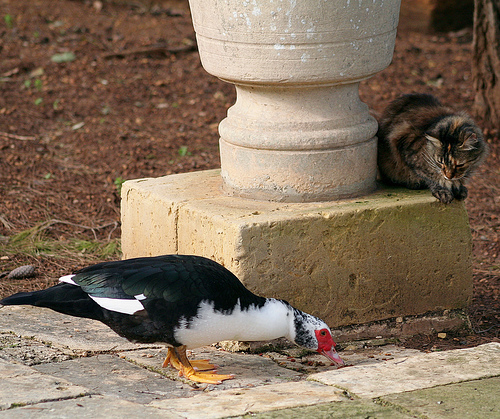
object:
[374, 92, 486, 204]
cat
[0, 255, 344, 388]
duck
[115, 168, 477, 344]
block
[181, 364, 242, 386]
feet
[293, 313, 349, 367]
head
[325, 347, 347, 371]
beak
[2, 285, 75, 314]
tail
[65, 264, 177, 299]
wings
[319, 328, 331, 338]
right eye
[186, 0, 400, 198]
pot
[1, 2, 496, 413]
ground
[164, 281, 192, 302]
feather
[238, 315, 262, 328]
feather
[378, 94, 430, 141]
stripes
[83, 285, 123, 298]
feather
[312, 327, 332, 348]
marking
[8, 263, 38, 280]
pine cone